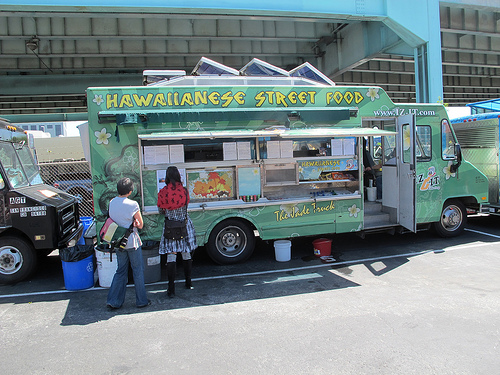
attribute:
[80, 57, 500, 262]
food truck — green, parked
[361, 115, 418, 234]
door — open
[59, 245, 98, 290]
garbage can — blue, recycling can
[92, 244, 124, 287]
garbage can — white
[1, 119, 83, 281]
truck — brown, black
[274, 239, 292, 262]
bucket — white, red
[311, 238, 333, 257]
bucket — red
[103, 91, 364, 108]
text — yellow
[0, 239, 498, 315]
stripe — white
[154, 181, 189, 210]
sweater — red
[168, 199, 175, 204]
dot — black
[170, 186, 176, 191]
dot — black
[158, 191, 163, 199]
dot — black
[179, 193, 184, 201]
dot — black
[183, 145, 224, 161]
window — small